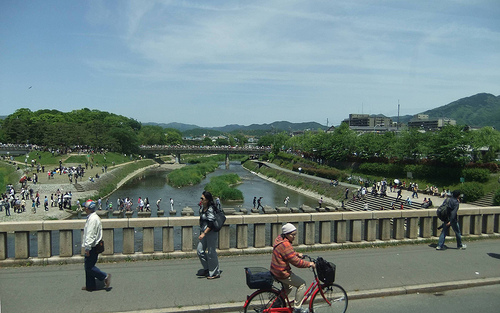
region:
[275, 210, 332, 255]
the hat is white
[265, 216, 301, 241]
the hat is white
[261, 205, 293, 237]
the hat is white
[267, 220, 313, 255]
the hat is white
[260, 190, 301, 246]
the hat is white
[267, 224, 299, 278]
the hat is white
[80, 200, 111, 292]
This is a man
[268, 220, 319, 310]
This is a boy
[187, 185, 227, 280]
This is a woman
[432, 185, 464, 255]
This is a woman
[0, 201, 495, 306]
This is a water bridge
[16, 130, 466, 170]
This is a water bridge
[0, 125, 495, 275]
These are people walking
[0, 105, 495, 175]
These are big trees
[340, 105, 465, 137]
These are buildings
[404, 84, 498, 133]
This is a hill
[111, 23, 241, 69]
clouds in the sky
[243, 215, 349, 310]
a person a bicycle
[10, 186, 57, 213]
a crowd of people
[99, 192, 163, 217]
people crossing the water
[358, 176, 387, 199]
a crowd of people on steps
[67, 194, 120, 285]
a person wearing white and black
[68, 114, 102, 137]
the leaves of trees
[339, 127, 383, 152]
the leaves of trees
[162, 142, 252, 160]
a bridge over water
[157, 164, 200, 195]
trees in the water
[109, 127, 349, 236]
a long water way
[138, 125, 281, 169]
a high cement bridge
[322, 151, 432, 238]
a set of cement stairs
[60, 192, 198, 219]
stepping stones in the river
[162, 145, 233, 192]
a grass covered island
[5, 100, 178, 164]
a bunch of tres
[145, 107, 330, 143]
a distant mountain range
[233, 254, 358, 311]
a bright red bike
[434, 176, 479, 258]
a man with a backpack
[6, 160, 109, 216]
a group of pedestrians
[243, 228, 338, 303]
person riding a bicycle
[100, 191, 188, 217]
people walking on cement step in water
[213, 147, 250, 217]
land in the middle of water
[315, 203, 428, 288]
bridge over the water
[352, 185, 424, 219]
steps from water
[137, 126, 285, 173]
bridge over the water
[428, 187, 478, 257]
man carrying backpack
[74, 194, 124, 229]
man is wearing a ball cap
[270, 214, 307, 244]
person wearing a hat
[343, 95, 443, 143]
buildings above the bridge